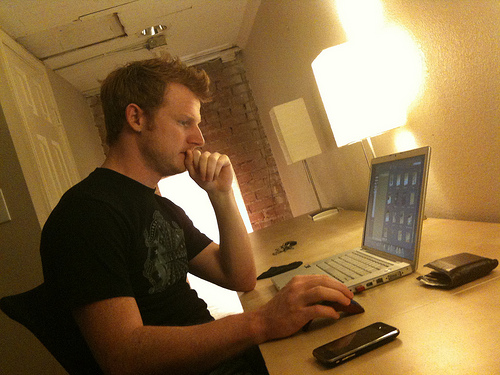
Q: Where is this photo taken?
A: Inside of a room.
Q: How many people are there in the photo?
A: One.